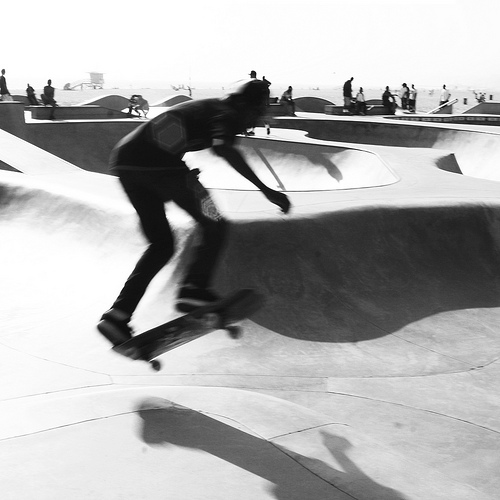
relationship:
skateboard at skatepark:
[107, 267, 265, 384] [20, 13, 437, 470]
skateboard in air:
[107, 267, 265, 384] [156, 286, 291, 410]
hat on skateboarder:
[243, 70, 287, 140] [121, 8, 297, 336]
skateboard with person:
[107, 267, 265, 384] [336, 68, 381, 124]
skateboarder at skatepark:
[121, 8, 297, 336] [20, 13, 437, 470]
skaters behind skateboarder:
[326, 81, 498, 106] [121, 8, 297, 336]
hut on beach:
[81, 61, 100, 100] [103, 16, 373, 100]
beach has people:
[103, 16, 373, 100] [316, 75, 451, 111]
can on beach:
[313, 79, 327, 93] [103, 16, 373, 100]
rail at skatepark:
[407, 110, 499, 131] [20, 13, 437, 470]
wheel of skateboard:
[222, 322, 248, 339] [107, 267, 265, 384]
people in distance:
[316, 75, 451, 111] [232, 61, 445, 130]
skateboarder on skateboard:
[96, 74, 297, 346] [107, 267, 265, 384]